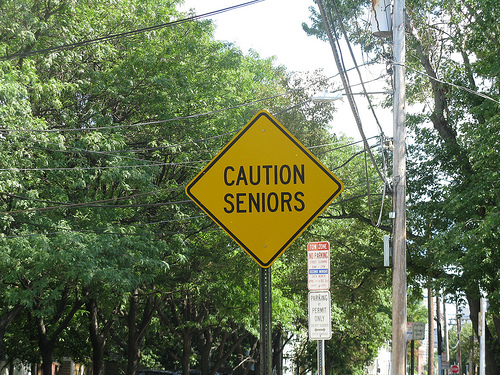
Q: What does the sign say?
A: Caution Seniors.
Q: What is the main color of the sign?
A: Yellow.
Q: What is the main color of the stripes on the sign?
A: Black.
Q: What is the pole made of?
A: Metal.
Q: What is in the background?
A: Trees.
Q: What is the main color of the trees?
A: Green.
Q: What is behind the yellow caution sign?
A: Street signs.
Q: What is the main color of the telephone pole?
A: Brown.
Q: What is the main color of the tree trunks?
A: Brown.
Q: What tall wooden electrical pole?
A: Pole with electrical wires.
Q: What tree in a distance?
A: Third green tree from left.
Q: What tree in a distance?
A: First tree from left of sign.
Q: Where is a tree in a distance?
A: First tree on right above lines.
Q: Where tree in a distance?
A: Right side of power pole.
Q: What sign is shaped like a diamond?
A: Yellow and black sign.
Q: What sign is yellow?
A: Caution sign.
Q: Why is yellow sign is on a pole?
A: Caution seniors.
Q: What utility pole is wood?
A: Pole that support power line.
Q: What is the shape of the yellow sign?
A: Diamond.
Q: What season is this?
A: Summer.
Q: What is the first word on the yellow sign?
A: Caution.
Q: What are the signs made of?
A: Metal.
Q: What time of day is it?
A: Daytime.